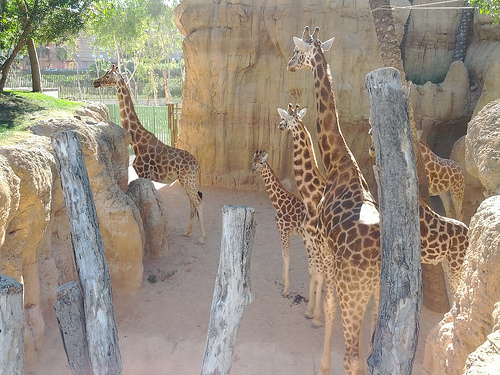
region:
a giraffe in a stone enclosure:
[90, 66, 211, 244]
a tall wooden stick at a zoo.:
[349, 59, 428, 372]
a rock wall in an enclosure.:
[412, 193, 497, 373]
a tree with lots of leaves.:
[0, 2, 87, 95]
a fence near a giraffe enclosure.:
[94, 105, 189, 162]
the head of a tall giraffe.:
[283, 28, 353, 88]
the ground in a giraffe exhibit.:
[0, 179, 454, 372]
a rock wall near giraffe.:
[0, 107, 166, 373]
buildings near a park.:
[0, 6, 182, 80]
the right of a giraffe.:
[299, 108, 312, 122]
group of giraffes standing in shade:
[89, 25, 442, 319]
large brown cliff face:
[11, 157, 53, 282]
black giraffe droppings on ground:
[273, 281, 312, 311]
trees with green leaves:
[0, 0, 172, 56]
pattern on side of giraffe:
[324, 207, 350, 239]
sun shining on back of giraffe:
[352, 191, 387, 239]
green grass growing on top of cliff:
[38, 96, 68, 108]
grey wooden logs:
[44, 133, 114, 373]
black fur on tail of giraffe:
[191, 186, 208, 203]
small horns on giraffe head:
[291, 22, 325, 39]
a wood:
[198, 190, 291, 315]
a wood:
[185, 228, 270, 350]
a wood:
[218, 193, 247, 334]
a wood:
[210, 207, 246, 292]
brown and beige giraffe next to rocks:
[85, 45, 200, 225]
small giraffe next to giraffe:
[242, 141, 298, 266]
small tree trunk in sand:
[211, 165, 252, 370]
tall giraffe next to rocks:
[295, 25, 381, 265]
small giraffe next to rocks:
[423, 115, 460, 205]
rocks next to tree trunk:
[450, 188, 486, 343]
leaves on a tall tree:
[16, 5, 66, 266]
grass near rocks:
[25, 77, 70, 108]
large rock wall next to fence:
[180, 8, 262, 130]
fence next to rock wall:
[148, 99, 179, 139]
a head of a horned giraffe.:
[89, 56, 132, 84]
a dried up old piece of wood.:
[184, 207, 269, 373]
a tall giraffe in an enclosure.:
[278, 13, 429, 373]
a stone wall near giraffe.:
[167, 3, 494, 204]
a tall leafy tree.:
[0, 0, 48, 94]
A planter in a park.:
[0, 87, 58, 105]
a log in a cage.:
[34, 129, 141, 374]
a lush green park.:
[0, 59, 178, 144]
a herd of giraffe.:
[81, 26, 477, 373]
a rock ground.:
[20, 180, 458, 373]